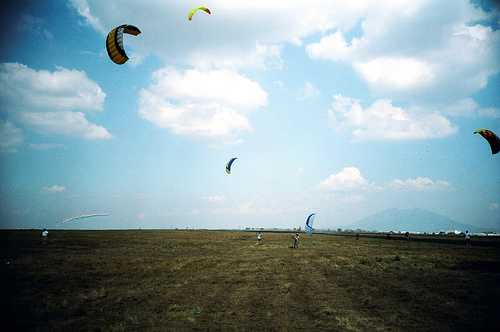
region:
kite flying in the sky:
[299, 206, 320, 240]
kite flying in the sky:
[54, 204, 108, 232]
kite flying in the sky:
[184, 2, 216, 24]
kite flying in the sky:
[97, 23, 148, 68]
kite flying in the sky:
[470, 125, 499, 155]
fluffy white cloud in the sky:
[303, 159, 383, 203]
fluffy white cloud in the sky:
[140, 60, 273, 110]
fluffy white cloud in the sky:
[133, 93, 253, 143]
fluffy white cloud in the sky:
[0, 55, 114, 115]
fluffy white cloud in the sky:
[15, 105, 118, 149]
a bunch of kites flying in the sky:
[9, 0, 498, 257]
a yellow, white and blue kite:
[103, 20, 140, 64]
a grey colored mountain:
[336, 204, 495, 240]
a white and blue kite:
[298, 206, 319, 238]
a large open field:
[6, 219, 498, 326]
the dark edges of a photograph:
[1, 221, 175, 329]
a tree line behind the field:
[234, 218, 495, 240]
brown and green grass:
[76, 228, 448, 327]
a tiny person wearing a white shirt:
[37, 226, 52, 237]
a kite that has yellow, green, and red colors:
[183, 5, 210, 21]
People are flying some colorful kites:
[11, 10, 488, 316]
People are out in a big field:
[25, 5, 498, 315]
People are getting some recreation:
[12, 7, 497, 309]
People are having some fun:
[43, 13, 493, 315]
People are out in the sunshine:
[50, 18, 495, 303]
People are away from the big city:
[20, 15, 493, 317]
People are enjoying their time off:
[50, 5, 485, 316]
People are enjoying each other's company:
[36, 10, 497, 295]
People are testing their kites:
[35, 7, 493, 317]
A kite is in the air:
[73, 15, 165, 81]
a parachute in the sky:
[98, 23, 145, 86]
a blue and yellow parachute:
[219, 156, 244, 176]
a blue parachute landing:
[303, 211, 320, 234]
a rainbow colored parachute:
[175, 3, 217, 21]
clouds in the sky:
[262, 8, 490, 130]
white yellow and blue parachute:
[97, 25, 145, 64]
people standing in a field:
[250, 230, 309, 250]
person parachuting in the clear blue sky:
[184, 2, 215, 27]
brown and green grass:
[152, 250, 284, 286]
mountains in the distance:
[351, 203, 476, 235]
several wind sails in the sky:
[86, 5, 481, 230]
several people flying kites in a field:
[10, 223, 499, 268]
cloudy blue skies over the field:
[201, 49, 435, 151]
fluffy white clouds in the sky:
[13, 60, 120, 162]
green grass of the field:
[118, 255, 348, 315]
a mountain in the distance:
[348, 201, 465, 238]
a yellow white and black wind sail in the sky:
[93, 18, 156, 78]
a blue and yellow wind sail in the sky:
[218, 150, 250, 177]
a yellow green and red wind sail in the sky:
[183, 0, 221, 32]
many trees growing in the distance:
[239, 224, 377, 237]